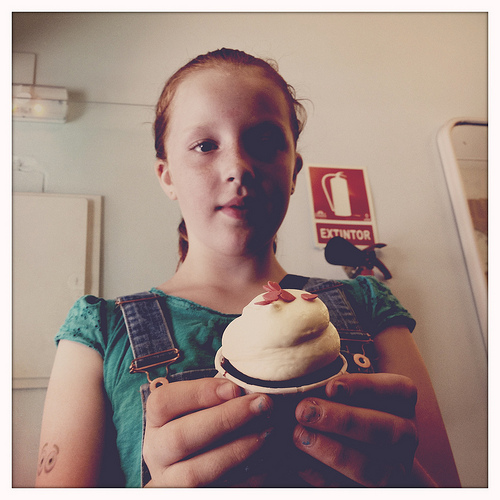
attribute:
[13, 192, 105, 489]
freezer — deep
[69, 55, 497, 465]
girl — brown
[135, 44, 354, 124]
hair — reddish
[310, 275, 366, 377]
overalls — blue, jean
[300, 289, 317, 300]
chip — chocolate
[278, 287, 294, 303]
chip — chocolate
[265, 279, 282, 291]
chip — chocolate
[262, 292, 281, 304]
chip — chocolate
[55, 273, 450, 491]
shirt — blue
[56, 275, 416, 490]
shirt — green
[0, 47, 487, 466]
wall — white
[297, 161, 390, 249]
sign — red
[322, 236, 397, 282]
extinguisher — fire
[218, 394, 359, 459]
polish — old, chipped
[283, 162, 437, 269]
sign — red, white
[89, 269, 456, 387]
shirt — green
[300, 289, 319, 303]
decoration — pink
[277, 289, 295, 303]
decoration — pink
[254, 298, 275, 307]
decoration — pink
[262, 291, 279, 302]
decoration — pink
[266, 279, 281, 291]
decoration — pink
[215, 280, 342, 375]
frosting — white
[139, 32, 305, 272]
hair — red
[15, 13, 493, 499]
wall — white